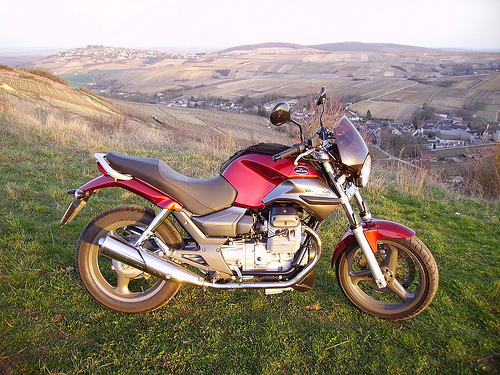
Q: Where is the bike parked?
A: Grassy hills.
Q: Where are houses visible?
A: At bottom of hill in valley.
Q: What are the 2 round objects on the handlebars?
A: Mirrors.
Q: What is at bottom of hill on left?
A: Houses.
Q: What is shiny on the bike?
A: Chrome.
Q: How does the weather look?
A: Hazy.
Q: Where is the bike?
A: On grass.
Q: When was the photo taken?
A: Afternoon.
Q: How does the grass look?
A: Green and sunlit.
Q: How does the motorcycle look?
A: Red.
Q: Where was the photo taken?
A: Hilly landscape.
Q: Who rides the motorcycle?
A: Rider.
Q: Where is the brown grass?
A: On hill.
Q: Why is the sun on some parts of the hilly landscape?
A: Setting.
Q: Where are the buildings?
A: On mountainside.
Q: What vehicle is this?
A: Motorcycle.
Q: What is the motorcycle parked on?
A: Grass.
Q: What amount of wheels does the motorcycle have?
A: Two.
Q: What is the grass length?
A: Cut.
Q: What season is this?
A: Summer.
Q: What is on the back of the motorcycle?
A: Exhaust pipe.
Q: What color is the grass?
A: Green.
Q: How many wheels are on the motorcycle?
A: Two.